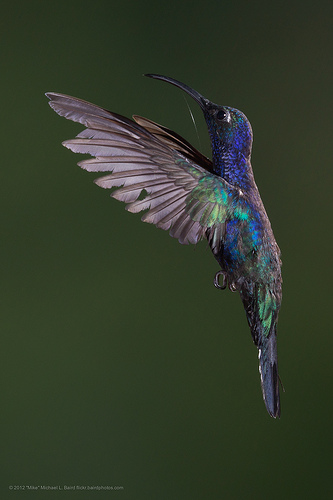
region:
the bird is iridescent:
[40, 70, 281, 417]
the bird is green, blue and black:
[40, 75, 287, 417]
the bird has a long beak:
[151, 73, 219, 114]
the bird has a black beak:
[151, 74, 214, 111]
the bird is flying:
[43, 73, 284, 420]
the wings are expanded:
[43, 91, 220, 247]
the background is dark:
[0, 0, 332, 499]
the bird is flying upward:
[44, 78, 279, 416]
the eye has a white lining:
[222, 108, 229, 122]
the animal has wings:
[45, 91, 243, 247]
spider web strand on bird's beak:
[174, 83, 212, 161]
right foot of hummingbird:
[212, 267, 227, 292]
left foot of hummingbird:
[229, 271, 239, 295]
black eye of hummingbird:
[214, 106, 232, 125]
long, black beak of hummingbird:
[140, 68, 207, 114]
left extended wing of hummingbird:
[42, 87, 240, 257]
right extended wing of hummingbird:
[127, 112, 213, 194]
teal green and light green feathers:
[193, 175, 227, 207]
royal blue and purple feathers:
[215, 124, 252, 181]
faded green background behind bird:
[50, 358, 217, 475]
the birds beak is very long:
[140, 71, 207, 103]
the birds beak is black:
[144, 70, 209, 110]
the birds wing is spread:
[37, 85, 227, 264]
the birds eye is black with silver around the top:
[210, 105, 231, 121]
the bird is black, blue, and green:
[144, 73, 298, 426]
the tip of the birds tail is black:
[255, 336, 283, 420]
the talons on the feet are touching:
[213, 266, 227, 294]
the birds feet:
[211, 265, 242, 304]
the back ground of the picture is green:
[6, 11, 327, 278]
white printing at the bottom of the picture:
[5, 485, 128, 494]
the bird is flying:
[99, 79, 313, 262]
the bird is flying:
[115, 29, 255, 311]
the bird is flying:
[107, 85, 209, 248]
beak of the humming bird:
[146, 53, 212, 112]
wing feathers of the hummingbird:
[43, 81, 199, 267]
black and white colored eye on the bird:
[211, 92, 237, 131]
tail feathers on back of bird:
[235, 279, 284, 431]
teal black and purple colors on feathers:
[242, 274, 281, 346]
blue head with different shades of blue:
[183, 92, 261, 174]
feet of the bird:
[211, 270, 240, 305]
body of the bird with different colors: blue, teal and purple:
[172, 146, 287, 320]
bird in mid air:
[54, 47, 289, 411]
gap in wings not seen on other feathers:
[101, 149, 159, 210]